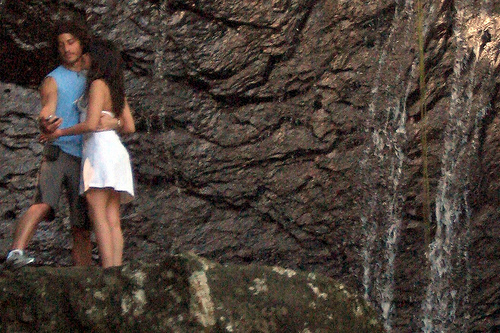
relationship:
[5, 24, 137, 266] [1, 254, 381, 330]
couple on rock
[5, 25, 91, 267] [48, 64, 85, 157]
man wearing shirt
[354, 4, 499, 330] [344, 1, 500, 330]
water falling from rock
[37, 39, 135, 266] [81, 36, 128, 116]
lady has hair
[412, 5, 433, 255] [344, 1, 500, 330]
growth on rock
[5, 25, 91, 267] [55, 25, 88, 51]
man has hair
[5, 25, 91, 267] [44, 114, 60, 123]
man has phone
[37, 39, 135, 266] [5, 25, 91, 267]
lady kisses man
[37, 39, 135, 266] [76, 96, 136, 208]
lady wears dress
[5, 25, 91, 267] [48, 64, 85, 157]
man wears shirt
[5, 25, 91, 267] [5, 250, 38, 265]
man wearing sneakers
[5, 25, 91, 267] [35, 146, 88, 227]
man wears shorts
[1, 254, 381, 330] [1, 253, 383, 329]
rock has moss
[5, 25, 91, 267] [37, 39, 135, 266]
man embraces lady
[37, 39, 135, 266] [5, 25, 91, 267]
lady embraces man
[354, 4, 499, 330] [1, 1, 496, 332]
water flows down rock wall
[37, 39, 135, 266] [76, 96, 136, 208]
lady wearing dress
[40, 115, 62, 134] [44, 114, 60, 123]
hand holding phone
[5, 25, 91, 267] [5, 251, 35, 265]
man has foot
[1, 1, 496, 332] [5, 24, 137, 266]
rock wall surround couple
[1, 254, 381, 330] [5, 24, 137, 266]
rock supports couple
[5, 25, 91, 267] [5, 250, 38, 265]
man wears sneakers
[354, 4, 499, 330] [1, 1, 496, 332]
water drips down rock wall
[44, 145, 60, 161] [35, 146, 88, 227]
phone holder on shorts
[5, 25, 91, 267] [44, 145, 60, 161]
man wears phone holder